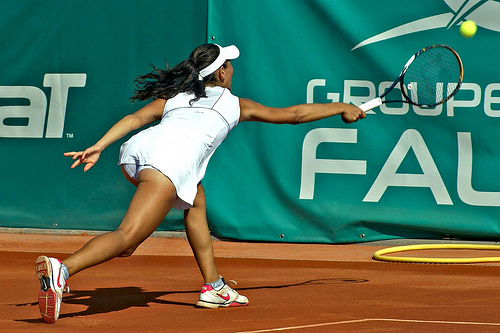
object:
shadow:
[11, 274, 288, 331]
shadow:
[270, 274, 371, 290]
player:
[32, 41, 366, 323]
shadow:
[0, 277, 371, 323]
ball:
[457, 19, 477, 39]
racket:
[358, 44, 465, 113]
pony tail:
[124, 58, 209, 108]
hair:
[125, 43, 228, 108]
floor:
[0, 228, 499, 332]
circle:
[372, 243, 499, 264]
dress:
[117, 84, 241, 210]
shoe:
[196, 274, 249, 309]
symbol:
[216, 293, 230, 304]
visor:
[194, 43, 240, 81]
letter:
[297, 127, 368, 200]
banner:
[0, 0, 499, 243]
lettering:
[0, 86, 48, 140]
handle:
[358, 96, 382, 113]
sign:
[55, 268, 63, 289]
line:
[231, 317, 499, 332]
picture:
[1, 0, 499, 332]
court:
[0, 0, 499, 332]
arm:
[239, 97, 341, 125]